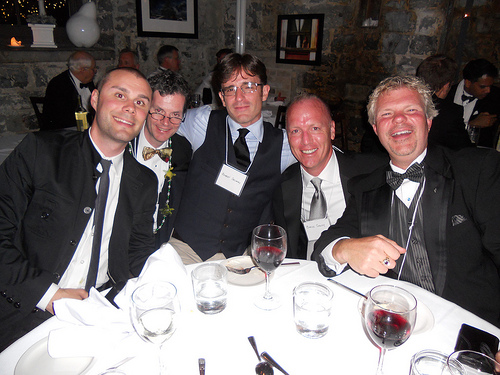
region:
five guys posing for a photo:
[3, 49, 494, 331]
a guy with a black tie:
[3, 71, 156, 305]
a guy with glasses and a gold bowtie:
[129, 68, 193, 250]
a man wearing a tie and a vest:
[189, 51, 285, 266]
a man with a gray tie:
[273, 92, 368, 277]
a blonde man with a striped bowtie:
[319, 74, 493, 304]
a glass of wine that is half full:
[247, 222, 289, 311]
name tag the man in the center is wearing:
[214, 162, 249, 197]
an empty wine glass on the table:
[129, 282, 183, 373]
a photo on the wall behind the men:
[276, 14, 323, 66]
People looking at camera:
[0, 55, 499, 351]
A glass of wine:
[364, 284, 416, 374]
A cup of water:
[293, 281, 332, 338]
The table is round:
[0, 256, 498, 374]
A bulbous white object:
[67, 2, 99, 43]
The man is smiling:
[368, 74, 436, 155]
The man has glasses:
[220, 81, 265, 94]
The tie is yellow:
[142, 146, 169, 162]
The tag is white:
[215, 165, 246, 195]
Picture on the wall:
[275, 12, 322, 65]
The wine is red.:
[367, 281, 408, 346]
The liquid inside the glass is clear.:
[190, 266, 232, 317]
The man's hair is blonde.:
[367, 74, 437, 162]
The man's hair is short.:
[367, 72, 435, 163]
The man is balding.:
[284, 91, 339, 171]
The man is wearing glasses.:
[210, 50, 266, 124]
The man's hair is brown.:
[216, 51, 273, 121]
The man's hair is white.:
[61, 51, 99, 88]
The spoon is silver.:
[247, 331, 277, 373]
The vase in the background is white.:
[65, 3, 103, 46]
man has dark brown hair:
[197, 41, 272, 95]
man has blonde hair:
[349, 64, 446, 133]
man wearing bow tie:
[377, 154, 432, 192]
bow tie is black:
[378, 158, 437, 197]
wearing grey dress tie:
[297, 172, 337, 235]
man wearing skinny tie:
[77, 147, 114, 299]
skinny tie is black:
[79, 143, 119, 296]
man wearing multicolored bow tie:
[135, 138, 177, 168]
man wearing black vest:
[165, 96, 296, 265]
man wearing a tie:
[335, 67, 495, 272]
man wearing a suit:
[355, 70, 485, 292]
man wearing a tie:
[266, 91, 351, 241]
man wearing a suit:
[283, 75, 344, 230]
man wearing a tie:
[196, 45, 271, 220]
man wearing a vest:
[210, 46, 275, 216]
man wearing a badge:
[212, 55, 263, 222]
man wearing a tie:
[15, 68, 140, 330]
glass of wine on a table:
[245, 221, 290, 304]